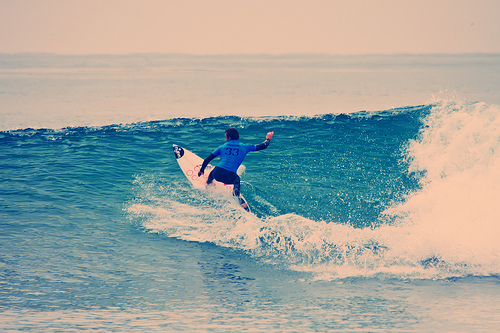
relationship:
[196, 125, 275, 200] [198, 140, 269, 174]
man has blue shirt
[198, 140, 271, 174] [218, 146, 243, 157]
blue shirt has numbers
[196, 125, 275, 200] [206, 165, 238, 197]
man on pant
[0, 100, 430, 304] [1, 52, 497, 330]
blue water on ocean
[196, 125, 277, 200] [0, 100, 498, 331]
man on wave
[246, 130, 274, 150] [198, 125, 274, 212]
arm of man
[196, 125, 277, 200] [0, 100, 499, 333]
man on blue water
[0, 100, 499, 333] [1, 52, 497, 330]
blue water on ocean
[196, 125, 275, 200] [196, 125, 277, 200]
man on man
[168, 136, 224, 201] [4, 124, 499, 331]
surfboard on ocean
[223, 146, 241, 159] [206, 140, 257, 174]
number on shirt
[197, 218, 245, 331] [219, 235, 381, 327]
reflection on water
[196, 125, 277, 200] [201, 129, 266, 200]
man wearing wetsuit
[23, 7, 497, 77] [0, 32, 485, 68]
sky above horizon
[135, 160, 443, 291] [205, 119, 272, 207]
wake created by surfer